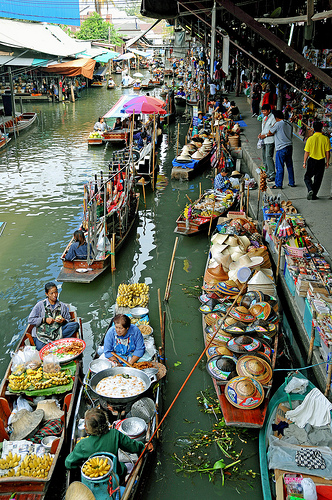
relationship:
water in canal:
[18, 105, 196, 493] [2, 3, 330, 498]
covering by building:
[46, 54, 96, 81] [61, 12, 111, 32]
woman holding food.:
[25, 281, 83, 350] [51, 311, 64, 321]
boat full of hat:
[200, 210, 280, 429] [236, 253, 263, 267]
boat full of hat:
[200, 210, 280, 429] [225, 335, 260, 353]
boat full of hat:
[200, 210, 280, 429] [206, 355, 239, 383]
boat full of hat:
[200, 210, 280, 429] [236, 355, 273, 383]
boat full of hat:
[200, 210, 280, 429] [224, 375, 264, 409]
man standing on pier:
[257, 108, 298, 192] [227, 89, 319, 274]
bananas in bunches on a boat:
[114, 281, 133, 294] [48, 161, 167, 289]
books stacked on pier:
[295, 272, 316, 297] [231, 92, 320, 378]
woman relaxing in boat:
[63, 227, 95, 263] [48, 173, 145, 281]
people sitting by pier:
[223, 100, 238, 121] [190, 90, 330, 302]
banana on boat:
[13, 453, 17, 461] [1, 302, 82, 497]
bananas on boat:
[5, 358, 73, 390] [0, 315, 84, 499]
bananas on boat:
[84, 452, 115, 477] [64, 282, 167, 499]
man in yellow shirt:
[300, 112, 328, 200] [297, 131, 330, 161]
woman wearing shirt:
[25, 281, 83, 345] [27, 297, 71, 343]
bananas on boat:
[5, 366, 73, 390] [1, 281, 83, 491]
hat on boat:
[210, 232, 228, 244] [200, 210, 280, 429]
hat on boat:
[225, 233, 240, 245] [200, 210, 280, 429]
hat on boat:
[234, 234, 250, 252] [200, 210, 280, 429]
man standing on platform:
[257, 103, 276, 180] [224, 91, 331, 261]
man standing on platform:
[257, 112, 296, 189] [224, 91, 331, 261]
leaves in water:
[182, 428, 263, 467] [6, 155, 95, 253]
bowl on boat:
[88, 360, 151, 406] [64, 282, 167, 499]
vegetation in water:
[173, 392, 254, 487] [0, 68, 263, 498]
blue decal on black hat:
[206, 352, 237, 377] [206, 353, 240, 382]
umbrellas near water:
[113, 70, 172, 139] [0, 68, 263, 498]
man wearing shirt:
[300, 112, 332, 205] [304, 131, 330, 159]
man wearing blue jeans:
[257, 108, 298, 192] [272, 143, 297, 187]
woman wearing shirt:
[104, 314, 145, 365] [102, 326, 144, 357]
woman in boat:
[104, 314, 145, 365] [75, 282, 163, 403]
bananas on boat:
[115, 278, 150, 309] [49, 313, 175, 492]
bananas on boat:
[84, 452, 115, 477] [49, 313, 175, 492]